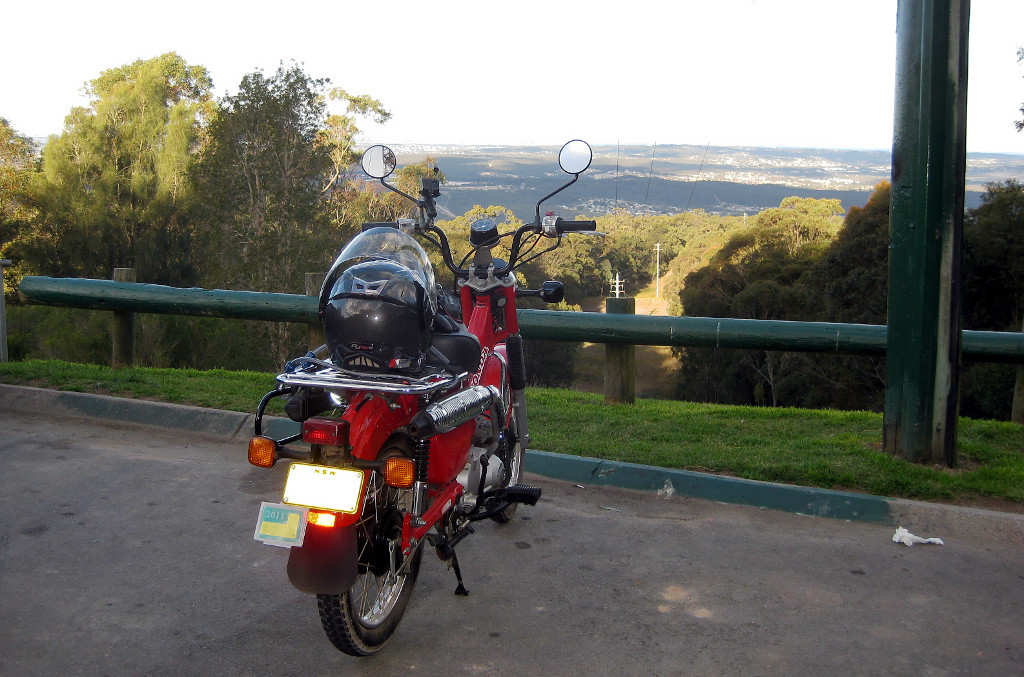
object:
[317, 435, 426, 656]
tire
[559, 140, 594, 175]
mirror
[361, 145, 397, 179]
bike mirror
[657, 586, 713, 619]
sunlight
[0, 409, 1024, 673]
road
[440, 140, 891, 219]
valley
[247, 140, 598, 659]
bike